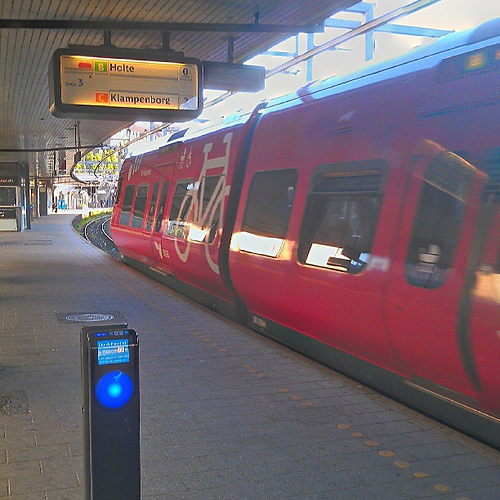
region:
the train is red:
[96, 138, 488, 381]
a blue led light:
[83, 362, 157, 422]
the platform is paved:
[175, 324, 312, 466]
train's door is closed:
[133, 149, 178, 279]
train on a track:
[106, 92, 493, 399]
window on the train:
[246, 170, 464, 277]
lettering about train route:
[66, 61, 191, 108]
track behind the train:
[84, 205, 107, 241]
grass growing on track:
[78, 203, 85, 238]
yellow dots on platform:
[276, 382, 358, 445]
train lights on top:
[448, 50, 498, 77]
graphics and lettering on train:
[121, 144, 156, 190]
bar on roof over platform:
[3, 8, 329, 46]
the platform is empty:
[40, 206, 173, 355]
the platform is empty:
[27, 170, 254, 442]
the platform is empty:
[21, 170, 256, 495]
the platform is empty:
[27, 171, 277, 497]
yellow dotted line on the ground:
[253, 371, 385, 496]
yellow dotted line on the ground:
[185, 326, 351, 476]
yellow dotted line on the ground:
[183, 330, 355, 465]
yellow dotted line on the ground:
[211, 319, 350, 479]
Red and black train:
[111, 15, 498, 449]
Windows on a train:
[117, 148, 499, 290]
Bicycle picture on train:
[173, 130, 240, 276]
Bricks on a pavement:
[1, 227, 496, 497]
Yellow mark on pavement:
[73, 215, 460, 493]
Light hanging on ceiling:
[46, 43, 203, 122]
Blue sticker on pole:
[95, 338, 131, 366]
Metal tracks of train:
[84, 210, 116, 250]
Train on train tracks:
[108, 10, 498, 442]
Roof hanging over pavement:
[1, 0, 336, 168]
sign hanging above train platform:
[49, 42, 204, 119]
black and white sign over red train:
[48, 44, 238, 277]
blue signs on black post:
[83, 326, 141, 498]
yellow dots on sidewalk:
[322, 414, 425, 494]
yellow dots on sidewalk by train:
[103, 139, 298, 416]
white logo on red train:
[163, 122, 239, 290]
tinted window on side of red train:
[289, 147, 398, 279]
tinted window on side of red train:
[235, 156, 312, 266]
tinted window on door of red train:
[399, 134, 486, 298]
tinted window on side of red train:
[117, 179, 134, 233]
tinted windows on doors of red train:
[144, 169, 169, 244]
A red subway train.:
[121, 57, 498, 395]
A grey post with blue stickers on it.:
[76, 320, 155, 498]